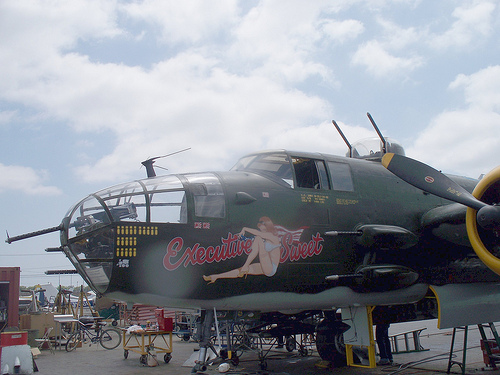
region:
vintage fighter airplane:
[25, 105, 460, 366]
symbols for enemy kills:
[111, 216, 161, 261]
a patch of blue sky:
[2, 116, 97, 166]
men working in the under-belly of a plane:
[305, 287, 401, 372]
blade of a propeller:
[377, 137, 492, 227]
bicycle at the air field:
[56, 306, 126, 357]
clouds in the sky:
[146, 61, 322, 131]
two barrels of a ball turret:
[320, 97, 411, 168]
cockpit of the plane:
[230, 135, 355, 210]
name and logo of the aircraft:
[161, 216, 326, 287]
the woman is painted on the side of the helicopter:
[196, 215, 314, 300]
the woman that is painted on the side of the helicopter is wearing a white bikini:
[261, 237, 293, 284]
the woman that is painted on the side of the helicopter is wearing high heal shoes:
[194, 211, 293, 293]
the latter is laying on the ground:
[370, 326, 437, 366]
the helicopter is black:
[4, 102, 498, 372]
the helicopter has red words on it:
[158, 226, 329, 278]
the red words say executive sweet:
[151, 228, 330, 274]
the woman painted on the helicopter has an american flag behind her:
[253, 215, 308, 248]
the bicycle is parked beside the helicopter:
[61, 315, 126, 354]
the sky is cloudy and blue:
[1, 0, 498, 329]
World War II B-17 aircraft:
[6, 101, 488, 341]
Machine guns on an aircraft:
[326, 103, 407, 149]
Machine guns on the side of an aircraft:
[317, 220, 422, 303]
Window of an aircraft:
[282, 152, 332, 197]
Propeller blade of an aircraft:
[375, 148, 465, 205]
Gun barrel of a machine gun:
[0, 222, 52, 247]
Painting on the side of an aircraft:
[231, 210, 306, 291]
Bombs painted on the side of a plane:
[111, 222, 161, 257]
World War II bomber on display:
[10, 97, 480, 358]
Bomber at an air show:
[20, 102, 470, 354]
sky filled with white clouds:
[0, 0, 498, 104]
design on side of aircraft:
[110, 217, 160, 272]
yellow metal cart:
[116, 322, 183, 364]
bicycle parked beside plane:
[60, 312, 121, 352]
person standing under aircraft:
[372, 301, 398, 364]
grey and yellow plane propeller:
[378, 150, 479, 221]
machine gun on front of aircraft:
[4, 204, 138, 250]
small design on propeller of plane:
[415, 172, 439, 187]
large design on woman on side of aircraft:
[161, 219, 332, 288]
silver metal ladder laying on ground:
[392, 322, 432, 359]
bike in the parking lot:
[63, 315, 122, 353]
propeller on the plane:
[371, 148, 496, 206]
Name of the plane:
[159, 209, 332, 289]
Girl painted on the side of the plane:
[239, 213, 288, 287]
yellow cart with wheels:
[114, 327, 179, 366]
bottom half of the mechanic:
[374, 302, 414, 374]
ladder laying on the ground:
[396, 324, 433, 357]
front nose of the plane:
[36, 176, 151, 305]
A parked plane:
[40, 108, 498, 358]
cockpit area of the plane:
[229, 148, 371, 205]